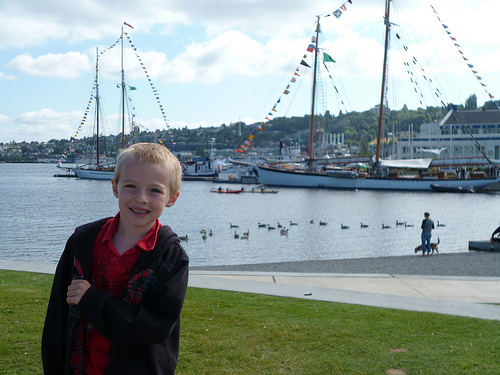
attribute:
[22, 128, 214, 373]
boy — young 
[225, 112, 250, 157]
tower — white , Thin 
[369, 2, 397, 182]
mast — Tall 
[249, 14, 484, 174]
flags — decorative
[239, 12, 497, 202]
ship — on right, sailing ship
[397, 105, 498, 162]
building — Large 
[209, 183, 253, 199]
kayak — Red 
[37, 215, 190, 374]
coat — dark , long 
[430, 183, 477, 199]
boat — Small 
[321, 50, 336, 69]
flag — small, green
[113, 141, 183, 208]
hair — blonde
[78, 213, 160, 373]
shirt — red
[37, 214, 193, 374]
sweatshirt — black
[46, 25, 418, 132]
banners — colored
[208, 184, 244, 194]
boat — small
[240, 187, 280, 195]
boat — small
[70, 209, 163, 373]
shirt — red 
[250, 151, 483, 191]
longboat — large, in background